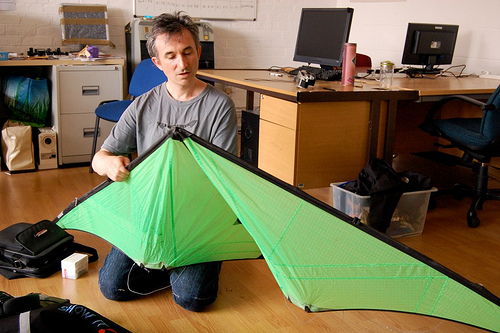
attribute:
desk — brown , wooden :
[200, 50, 446, 191]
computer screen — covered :
[57, 2, 113, 44]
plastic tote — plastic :
[329, 182, 438, 236]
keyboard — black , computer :
[275, 54, 342, 89]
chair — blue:
[406, 52, 498, 196]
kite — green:
[54, 124, 498, 329]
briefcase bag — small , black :
[6, 207, 75, 289]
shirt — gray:
[102, 80, 239, 160]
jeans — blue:
[102, 241, 217, 307]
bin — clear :
[327, 180, 436, 240]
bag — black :
[0, 216, 100, 278]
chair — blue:
[420, 92, 499, 229]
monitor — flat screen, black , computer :
[288, 6, 356, 68]